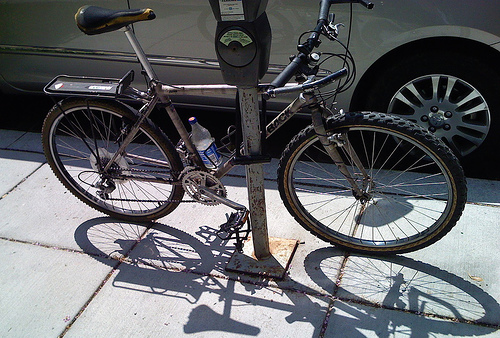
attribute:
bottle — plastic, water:
[185, 117, 221, 169]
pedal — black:
[224, 208, 249, 234]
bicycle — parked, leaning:
[35, 0, 470, 259]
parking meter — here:
[204, 0, 274, 90]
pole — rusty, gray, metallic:
[226, 85, 301, 281]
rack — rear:
[43, 69, 144, 101]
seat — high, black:
[73, 5, 165, 34]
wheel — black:
[353, 47, 499, 176]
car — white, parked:
[1, 0, 499, 176]